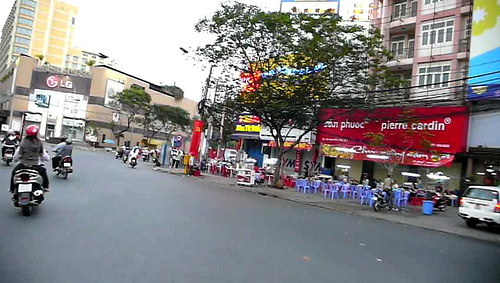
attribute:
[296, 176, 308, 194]
chair —  plastic and blue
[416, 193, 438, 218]
can — blue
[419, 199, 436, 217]
trash can — blue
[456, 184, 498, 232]
van — white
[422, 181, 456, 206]
bin — blue 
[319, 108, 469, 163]
sign — red, big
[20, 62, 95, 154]
lg store — black, white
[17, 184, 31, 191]
license plate — white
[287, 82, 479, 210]
store — red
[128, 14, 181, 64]
sky — grey, white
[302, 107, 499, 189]
sign — red, white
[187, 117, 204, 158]
sign — red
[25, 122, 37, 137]
helmet — red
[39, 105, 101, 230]
bikes — motorized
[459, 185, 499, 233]
suv — white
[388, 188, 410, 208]
blue chair — plastic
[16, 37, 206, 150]
building — large, brown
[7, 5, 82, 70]
building — yellow, blue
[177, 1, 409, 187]
tree — large, green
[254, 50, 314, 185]
tree — green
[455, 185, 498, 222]
car — white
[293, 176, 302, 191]
chair — blue 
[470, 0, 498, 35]
flower — yellow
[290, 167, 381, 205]
chairs — blue 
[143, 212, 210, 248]
road — dark grey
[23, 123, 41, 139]
helmet — red